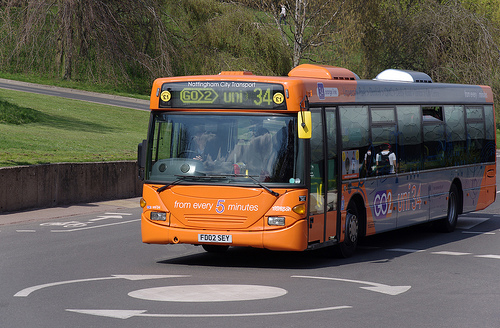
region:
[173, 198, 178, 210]
white letter on bus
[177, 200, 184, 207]
white letter on bus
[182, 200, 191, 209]
white letter on bus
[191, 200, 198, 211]
white letter on bus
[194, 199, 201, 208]
white letter on bus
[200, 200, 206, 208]
white letter on bus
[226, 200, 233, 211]
white letter on bus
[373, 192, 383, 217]
white letter on bus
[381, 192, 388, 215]
white letter on bus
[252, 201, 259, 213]
white letter on bus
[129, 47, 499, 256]
orange and blue bus on road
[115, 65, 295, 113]
electronic information display above windshield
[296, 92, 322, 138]
yellow side mirror on bus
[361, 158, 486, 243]
ad on side of bus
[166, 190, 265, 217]
ad on front of bus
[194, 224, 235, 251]
tag on front of orange bus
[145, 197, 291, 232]
orange buses headlights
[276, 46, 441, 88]
vents on top of bus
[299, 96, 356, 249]
door of the bus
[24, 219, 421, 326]
round about sign on road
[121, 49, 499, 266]
A orange public bus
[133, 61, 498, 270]
A orange public bus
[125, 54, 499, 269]
A orange public bus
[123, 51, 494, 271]
A orange public bus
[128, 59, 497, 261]
A orange public bus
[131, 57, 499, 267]
A orange public bus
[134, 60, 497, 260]
A orange public bus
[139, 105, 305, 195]
window of a bus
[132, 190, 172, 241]
light of a bus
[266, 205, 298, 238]
light of a bus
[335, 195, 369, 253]
wheel of a bus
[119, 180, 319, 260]
bumper of a bus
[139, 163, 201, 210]
wiper of a bus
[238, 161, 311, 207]
window wiper of a bus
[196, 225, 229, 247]
plate of a bus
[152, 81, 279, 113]
display of a bus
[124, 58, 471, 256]
A bus riding on the street.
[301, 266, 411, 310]
White arrows on the road.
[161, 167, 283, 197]
Wipers on the windshield.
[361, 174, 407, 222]
GO2 written on the side of the bus.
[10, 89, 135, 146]
Green grass on the hill.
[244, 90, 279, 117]
The bus has number 34 written on it.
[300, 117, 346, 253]
The door of the bus.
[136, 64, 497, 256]
A commuter bus in transit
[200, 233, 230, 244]
The bus'es licence plate number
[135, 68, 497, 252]
An orange bus in transit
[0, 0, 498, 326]
A Nottingham city bus transport.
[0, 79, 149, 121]
The sloping road in the background.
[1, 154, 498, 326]
A clearly marked tarmacked road.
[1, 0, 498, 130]
The vegetation in the backlground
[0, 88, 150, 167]
The green grass on the sloping grounds.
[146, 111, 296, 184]
The front window windscreen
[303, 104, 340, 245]
The bus'es entry and exit front door.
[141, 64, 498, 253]
a bus riding down the street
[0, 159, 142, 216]
a concrete retaining wall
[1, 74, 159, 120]
a street on a hill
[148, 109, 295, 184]
a front windshield on a bus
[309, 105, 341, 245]
a door on a bus